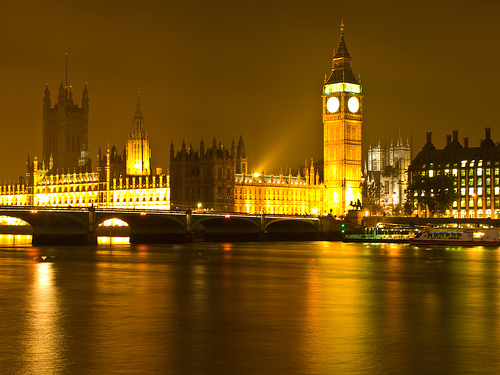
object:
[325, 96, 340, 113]
clock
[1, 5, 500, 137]
sky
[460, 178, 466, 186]
windows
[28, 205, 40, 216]
signal lights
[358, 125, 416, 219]
castle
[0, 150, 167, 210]
building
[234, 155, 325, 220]
building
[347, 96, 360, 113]
clock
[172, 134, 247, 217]
building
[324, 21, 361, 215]
building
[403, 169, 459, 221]
trees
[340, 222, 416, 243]
boat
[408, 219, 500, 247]
boat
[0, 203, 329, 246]
bridge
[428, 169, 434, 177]
windows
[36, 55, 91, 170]
building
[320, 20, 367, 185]
structure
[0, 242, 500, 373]
river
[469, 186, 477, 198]
lights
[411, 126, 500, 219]
building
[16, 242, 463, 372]
water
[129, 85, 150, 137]
roof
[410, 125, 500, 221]
multiple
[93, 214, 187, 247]
arch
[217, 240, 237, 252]
light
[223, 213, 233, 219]
light